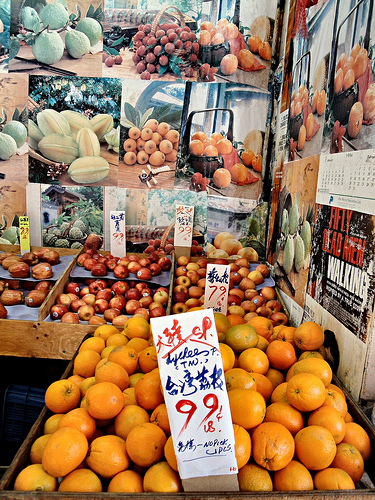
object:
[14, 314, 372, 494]
oranges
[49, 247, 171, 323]
apples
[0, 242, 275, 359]
blue trays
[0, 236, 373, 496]
crates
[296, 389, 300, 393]
end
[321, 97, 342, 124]
ground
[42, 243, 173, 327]
apples bin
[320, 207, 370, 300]
sign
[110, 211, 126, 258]
sign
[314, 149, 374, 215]
white/black print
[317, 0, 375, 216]
calendar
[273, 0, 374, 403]
wall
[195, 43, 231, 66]
basket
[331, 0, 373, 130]
basket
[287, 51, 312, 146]
basket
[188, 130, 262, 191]
oranges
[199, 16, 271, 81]
oranges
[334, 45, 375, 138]
oranges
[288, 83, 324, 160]
oranges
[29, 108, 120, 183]
starfruit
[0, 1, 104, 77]
pictures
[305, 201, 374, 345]
pictures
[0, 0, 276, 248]
wall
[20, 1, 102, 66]
pears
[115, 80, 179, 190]
poster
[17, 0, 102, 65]
green pears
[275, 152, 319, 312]
poster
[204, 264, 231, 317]
sign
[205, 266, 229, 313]
writing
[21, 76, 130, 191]
poster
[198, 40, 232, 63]
two people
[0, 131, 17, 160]
melons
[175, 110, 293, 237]
picture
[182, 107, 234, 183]
basket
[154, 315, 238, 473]
writing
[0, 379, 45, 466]
container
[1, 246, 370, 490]
fruit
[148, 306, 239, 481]
sign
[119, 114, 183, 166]
fruit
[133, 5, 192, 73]
basket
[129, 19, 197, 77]
grapes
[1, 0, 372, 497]
stand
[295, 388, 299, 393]
stem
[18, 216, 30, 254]
sign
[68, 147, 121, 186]
table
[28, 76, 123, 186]
pciture